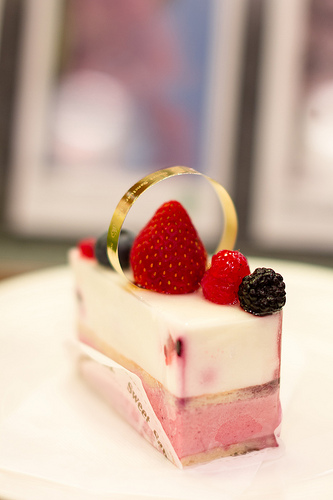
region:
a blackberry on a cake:
[240, 266, 288, 317]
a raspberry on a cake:
[200, 249, 250, 305]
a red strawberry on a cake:
[129, 199, 204, 292]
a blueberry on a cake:
[96, 226, 132, 269]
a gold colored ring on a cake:
[104, 162, 239, 291]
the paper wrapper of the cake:
[57, 329, 184, 471]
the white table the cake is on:
[0, 255, 328, 499]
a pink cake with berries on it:
[69, 163, 283, 454]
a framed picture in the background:
[13, 0, 245, 247]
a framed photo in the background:
[246, 0, 331, 251]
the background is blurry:
[19, 43, 316, 267]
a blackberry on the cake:
[222, 263, 287, 326]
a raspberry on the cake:
[195, 244, 249, 305]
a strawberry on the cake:
[126, 193, 198, 299]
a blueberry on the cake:
[93, 214, 135, 273]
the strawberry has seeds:
[127, 190, 205, 303]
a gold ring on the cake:
[77, 155, 238, 290]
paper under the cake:
[48, 321, 204, 477]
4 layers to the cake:
[158, 301, 282, 459]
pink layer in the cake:
[137, 391, 293, 451]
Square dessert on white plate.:
[0, 164, 331, 491]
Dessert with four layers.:
[65, 248, 286, 471]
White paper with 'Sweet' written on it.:
[67, 333, 178, 462]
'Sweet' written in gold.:
[120, 372, 147, 418]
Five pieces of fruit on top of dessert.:
[74, 197, 282, 312]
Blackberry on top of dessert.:
[232, 263, 281, 310]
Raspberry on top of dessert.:
[197, 247, 244, 296]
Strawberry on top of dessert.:
[126, 196, 201, 286]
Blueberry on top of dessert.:
[91, 224, 129, 266]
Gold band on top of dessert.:
[104, 161, 256, 279]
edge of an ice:
[196, 414, 204, 425]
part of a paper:
[143, 412, 149, 422]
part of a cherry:
[252, 294, 259, 306]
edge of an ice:
[185, 385, 194, 413]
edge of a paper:
[139, 400, 147, 414]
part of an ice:
[197, 333, 204, 344]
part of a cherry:
[178, 284, 184, 292]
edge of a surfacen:
[187, 400, 193, 410]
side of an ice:
[274, 427, 278, 437]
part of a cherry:
[228, 284, 233, 290]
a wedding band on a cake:
[99, 154, 250, 297]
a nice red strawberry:
[130, 200, 205, 293]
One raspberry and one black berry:
[200, 244, 292, 315]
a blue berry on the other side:
[96, 216, 138, 269]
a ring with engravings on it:
[103, 161, 236, 284]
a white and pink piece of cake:
[59, 266, 288, 462]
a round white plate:
[4, 241, 329, 498]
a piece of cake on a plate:
[24, 230, 317, 473]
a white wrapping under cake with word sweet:
[53, 336, 186, 473]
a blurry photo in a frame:
[12, 17, 241, 255]